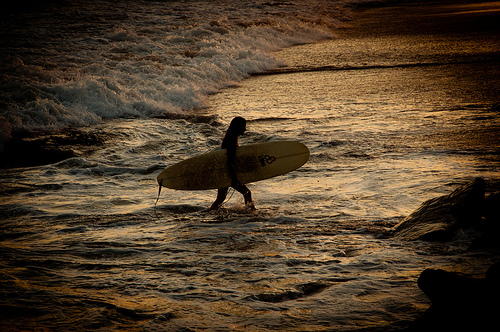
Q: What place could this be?
A: It is an ocean.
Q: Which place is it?
A: It is an ocean.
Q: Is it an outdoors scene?
A: Yes, it is outdoors.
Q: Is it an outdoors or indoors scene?
A: It is outdoors.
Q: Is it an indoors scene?
A: No, it is outdoors.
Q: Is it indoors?
A: No, it is outdoors.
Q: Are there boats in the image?
A: No, there are no boats.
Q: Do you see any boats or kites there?
A: No, there are no boats or kites.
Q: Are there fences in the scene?
A: No, there are no fences.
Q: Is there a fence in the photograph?
A: No, there are no fences.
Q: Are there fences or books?
A: No, there are no fences or books.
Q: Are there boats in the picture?
A: No, there are no boats.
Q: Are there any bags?
A: No, there are no bags.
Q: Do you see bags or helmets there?
A: No, there are no bags or helmets.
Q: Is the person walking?
A: Yes, the person is walking.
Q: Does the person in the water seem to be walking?
A: Yes, the person is walking.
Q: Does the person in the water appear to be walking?
A: Yes, the person is walking.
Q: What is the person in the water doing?
A: The person is walking.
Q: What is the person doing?
A: The person is walking.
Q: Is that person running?
A: No, the person is walking.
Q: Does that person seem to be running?
A: No, the person is walking.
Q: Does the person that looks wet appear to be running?
A: No, the person is walking.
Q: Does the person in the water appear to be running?
A: No, the person is walking.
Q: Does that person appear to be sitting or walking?
A: The person is walking.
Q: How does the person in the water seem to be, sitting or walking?
A: The person is walking.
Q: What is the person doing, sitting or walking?
A: The person is walking.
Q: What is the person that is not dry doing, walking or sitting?
A: The person is walking.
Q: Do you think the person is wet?
A: Yes, the person is wet.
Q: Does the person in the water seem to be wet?
A: Yes, the person is wet.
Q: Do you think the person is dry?
A: No, the person is wet.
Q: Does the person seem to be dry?
A: No, the person is wet.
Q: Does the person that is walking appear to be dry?
A: No, the person is wet.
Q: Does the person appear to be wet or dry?
A: The person is wet.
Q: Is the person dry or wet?
A: The person is wet.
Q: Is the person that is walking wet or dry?
A: The person is wet.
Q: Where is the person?
A: The person is in the water.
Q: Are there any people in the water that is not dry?
A: Yes, there is a person in the water.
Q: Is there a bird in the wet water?
A: No, there is a person in the water.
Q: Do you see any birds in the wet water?
A: No, there is a person in the water.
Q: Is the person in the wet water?
A: Yes, the person is in the water.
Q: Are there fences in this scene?
A: No, there are no fences.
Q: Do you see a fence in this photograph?
A: No, there are no fences.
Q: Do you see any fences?
A: No, there are no fences.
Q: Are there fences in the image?
A: No, there are no fences.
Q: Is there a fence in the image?
A: No, there are no fences.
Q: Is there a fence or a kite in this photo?
A: No, there are no fences or kites.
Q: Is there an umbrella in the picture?
A: No, there are no umbrellas.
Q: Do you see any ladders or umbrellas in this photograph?
A: No, there are no umbrellas or ladders.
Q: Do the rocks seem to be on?
A: Yes, the rocks are on.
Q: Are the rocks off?
A: No, the rocks are on.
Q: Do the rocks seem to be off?
A: No, the rocks are on.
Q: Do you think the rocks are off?
A: No, the rocks are on.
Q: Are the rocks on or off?
A: The rocks are on.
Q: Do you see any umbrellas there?
A: No, there are no umbrellas.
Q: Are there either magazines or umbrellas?
A: No, there are no umbrellas or magazines.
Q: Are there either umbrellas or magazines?
A: No, there are no umbrellas or magazines.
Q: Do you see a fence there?
A: No, there are no fences.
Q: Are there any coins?
A: No, there are no coins.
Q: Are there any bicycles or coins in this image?
A: No, there are no coins or bicycles.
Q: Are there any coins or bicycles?
A: No, there are no coins or bicycles.